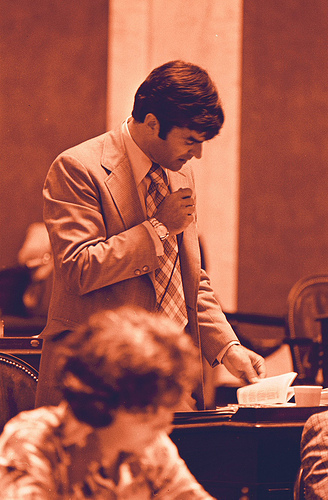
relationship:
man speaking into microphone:
[30, 56, 268, 435] [173, 186, 190, 194]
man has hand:
[30, 56, 276, 435] [213, 339, 265, 380]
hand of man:
[221, 341, 267, 388] [30, 56, 268, 435]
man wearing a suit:
[30, 56, 268, 435] [36, 121, 246, 411]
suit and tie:
[36, 121, 246, 411] [145, 162, 189, 332]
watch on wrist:
[147, 216, 172, 244] [149, 214, 170, 246]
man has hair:
[30, 56, 268, 435] [130, 59, 224, 140]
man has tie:
[30, 56, 268, 435] [145, 162, 189, 332]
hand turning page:
[221, 341, 269, 386] [234, 366, 300, 405]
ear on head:
[143, 112, 159, 138] [104, 39, 213, 187]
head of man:
[104, 39, 213, 187] [30, 56, 268, 435]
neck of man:
[122, 118, 178, 172] [30, 56, 268, 435]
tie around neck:
[143, 164, 193, 328] [122, 118, 178, 172]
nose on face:
[190, 139, 202, 159] [159, 120, 205, 173]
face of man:
[159, 120, 205, 173] [30, 56, 268, 435]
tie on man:
[143, 164, 190, 336] [36, 50, 258, 349]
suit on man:
[36, 121, 246, 411] [36, 50, 258, 349]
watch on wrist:
[148, 220, 173, 240] [155, 213, 174, 242]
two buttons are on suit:
[129, 261, 158, 277] [36, 119, 242, 410]